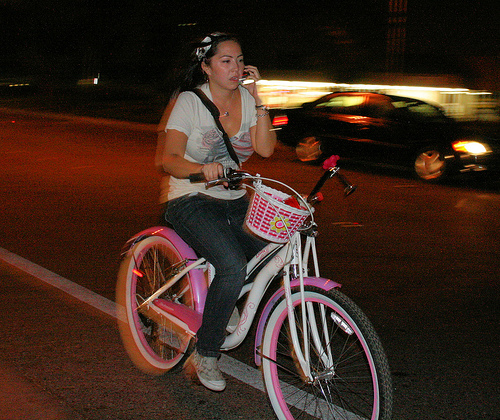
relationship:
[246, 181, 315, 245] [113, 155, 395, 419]
basket on bike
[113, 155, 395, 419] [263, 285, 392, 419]
bike has a tire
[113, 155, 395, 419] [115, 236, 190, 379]
bike has a tire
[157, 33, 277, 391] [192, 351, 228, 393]
woman wearing a shoe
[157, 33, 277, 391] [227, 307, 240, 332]
woman wearing a shoe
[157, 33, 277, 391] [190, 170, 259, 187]
woman holding handle bar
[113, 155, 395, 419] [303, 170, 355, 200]
bike has a handle bar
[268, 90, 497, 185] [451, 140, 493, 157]
car has a headlight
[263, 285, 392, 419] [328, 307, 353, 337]
tire has a reflector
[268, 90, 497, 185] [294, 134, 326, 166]
car has a tire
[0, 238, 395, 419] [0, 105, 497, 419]
line on street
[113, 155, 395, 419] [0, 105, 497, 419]
bike on street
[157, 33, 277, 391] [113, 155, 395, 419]
woman riding bike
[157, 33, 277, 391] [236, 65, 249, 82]
woman using a cell phone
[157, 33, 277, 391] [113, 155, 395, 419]
woman riding a bike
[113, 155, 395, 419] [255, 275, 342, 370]
bike has fender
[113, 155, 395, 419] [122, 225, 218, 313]
bike has fender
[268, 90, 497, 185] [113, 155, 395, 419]
car next to bike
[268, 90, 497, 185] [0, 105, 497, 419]
car on street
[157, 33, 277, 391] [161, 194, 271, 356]
woman wearing jeans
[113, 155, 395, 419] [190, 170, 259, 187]
bike has a handle bar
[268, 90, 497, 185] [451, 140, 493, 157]
car has headlight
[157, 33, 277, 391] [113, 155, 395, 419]
woman on bike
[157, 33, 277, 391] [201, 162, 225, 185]
woman has a hand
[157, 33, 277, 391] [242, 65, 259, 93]
woman has a hand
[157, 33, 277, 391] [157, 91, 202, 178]
woman has an arm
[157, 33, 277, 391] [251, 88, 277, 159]
woman has an arm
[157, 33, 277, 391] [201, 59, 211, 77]
woman has an ear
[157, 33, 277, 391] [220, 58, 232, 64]
woman has an eye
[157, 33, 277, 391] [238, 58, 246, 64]
woman has an eye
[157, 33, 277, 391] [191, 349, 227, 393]
woman has a foot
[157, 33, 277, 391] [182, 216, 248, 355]
woman has a leg